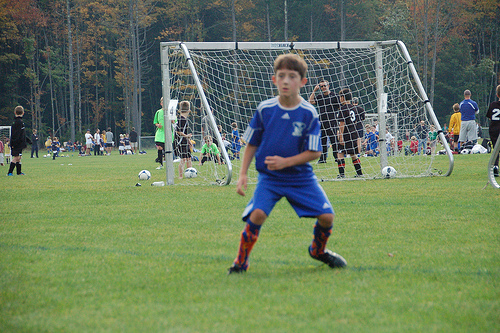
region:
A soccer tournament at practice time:
[0, 1, 497, 330]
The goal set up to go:
[157, 39, 453, 184]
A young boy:
[234, 53, 347, 272]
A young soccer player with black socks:
[9, 103, 25, 173]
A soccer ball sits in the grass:
[134, 167, 151, 182]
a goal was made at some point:
[380, 165, 397, 180]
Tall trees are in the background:
[124, 0, 142, 150]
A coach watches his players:
[459, 88, 479, 151]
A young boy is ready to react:
[222, 55, 350, 267]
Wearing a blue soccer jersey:
[227, 47, 347, 270]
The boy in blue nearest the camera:
[218, 49, 355, 276]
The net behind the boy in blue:
[154, 36, 456, 183]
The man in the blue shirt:
[454, 89, 484, 150]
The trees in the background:
[0, 1, 499, 146]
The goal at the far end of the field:
[0, 123, 18, 160]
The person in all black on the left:
[3, 104, 31, 176]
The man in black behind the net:
[309, 76, 342, 163]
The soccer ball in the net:
[374, 161, 407, 183]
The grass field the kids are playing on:
[1, 148, 499, 331]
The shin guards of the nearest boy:
[227, 218, 332, 261]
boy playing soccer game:
[233, 45, 365, 303]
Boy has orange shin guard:
[227, 212, 277, 282]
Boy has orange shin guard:
[303, 220, 332, 264]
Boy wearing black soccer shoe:
[224, 260, 258, 287]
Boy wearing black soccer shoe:
[306, 242, 349, 272]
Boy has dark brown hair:
[261, 50, 323, 78]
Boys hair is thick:
[273, 51, 308, 81]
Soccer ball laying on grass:
[131, 162, 156, 193]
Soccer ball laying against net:
[378, 159, 405, 191]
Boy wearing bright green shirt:
[151, 103, 177, 147]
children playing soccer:
[11, 26, 481, 310]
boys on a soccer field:
[10, 24, 492, 281]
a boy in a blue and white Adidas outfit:
[203, 43, 367, 295]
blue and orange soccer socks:
[217, 209, 365, 291]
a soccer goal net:
[144, 31, 485, 209]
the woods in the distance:
[4, 2, 492, 153]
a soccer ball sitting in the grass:
[128, 163, 152, 185]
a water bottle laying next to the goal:
[147, 179, 170, 190]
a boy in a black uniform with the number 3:
[332, 82, 375, 187]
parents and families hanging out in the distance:
[29, 114, 147, 164]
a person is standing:
[0, 96, 30, 180]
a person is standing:
[223, 50, 350, 269]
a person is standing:
[332, 85, 365, 184]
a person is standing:
[307, 75, 335, 164]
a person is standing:
[456, 89, 476, 147]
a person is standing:
[480, 82, 499, 160]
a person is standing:
[444, 95, 460, 145]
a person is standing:
[153, 96, 173, 165]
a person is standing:
[173, 97, 193, 175]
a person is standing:
[84, 125, 91, 149]